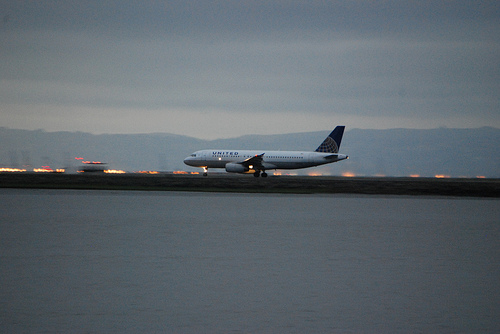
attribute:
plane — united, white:
[181, 123, 352, 181]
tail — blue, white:
[313, 125, 350, 158]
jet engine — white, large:
[221, 160, 249, 173]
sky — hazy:
[171, 31, 334, 89]